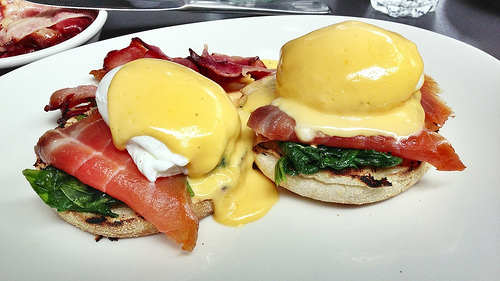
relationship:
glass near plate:
[373, 1, 435, 13] [25, 15, 490, 281]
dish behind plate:
[0, 8, 111, 69] [25, 15, 490, 281]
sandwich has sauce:
[62, 29, 413, 239] [123, 27, 416, 187]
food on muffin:
[94, 39, 198, 202] [35, 202, 224, 244]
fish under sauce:
[247, 108, 460, 176] [123, 27, 416, 187]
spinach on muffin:
[34, 143, 115, 218] [35, 202, 224, 244]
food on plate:
[94, 39, 198, 202] [25, 15, 490, 281]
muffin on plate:
[35, 202, 224, 244] [25, 15, 490, 281]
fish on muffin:
[247, 108, 460, 176] [35, 202, 224, 244]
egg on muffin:
[99, 81, 176, 156] [35, 202, 224, 244]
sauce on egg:
[123, 27, 416, 187] [99, 81, 176, 156]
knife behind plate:
[58, 1, 324, 17] [25, 15, 490, 281]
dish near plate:
[1, 14, 112, 63] [25, 15, 490, 281]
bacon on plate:
[116, 33, 283, 90] [25, 15, 490, 281]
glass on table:
[373, 1, 435, 13] [439, 1, 499, 68]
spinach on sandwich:
[34, 143, 115, 218] [62, 29, 413, 239]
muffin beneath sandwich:
[35, 202, 224, 244] [62, 29, 413, 239]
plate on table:
[25, 15, 490, 281] [439, 1, 499, 68]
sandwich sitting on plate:
[62, 29, 413, 239] [25, 15, 490, 281]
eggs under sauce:
[107, 61, 220, 177] [123, 27, 416, 187]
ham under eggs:
[65, 62, 272, 117] [107, 61, 220, 177]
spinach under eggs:
[34, 143, 115, 218] [107, 61, 220, 177]